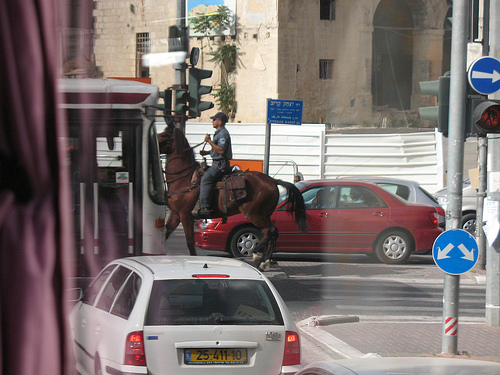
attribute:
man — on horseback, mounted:
[200, 104, 236, 181]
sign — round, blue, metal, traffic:
[434, 228, 480, 271]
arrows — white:
[440, 242, 476, 262]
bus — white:
[21, 85, 165, 265]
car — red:
[226, 185, 438, 268]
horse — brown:
[167, 155, 268, 239]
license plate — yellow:
[176, 349, 256, 367]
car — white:
[106, 269, 285, 373]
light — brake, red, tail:
[277, 331, 310, 372]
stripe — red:
[33, 87, 161, 110]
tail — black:
[271, 172, 316, 242]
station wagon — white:
[94, 251, 286, 374]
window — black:
[154, 287, 262, 315]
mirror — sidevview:
[65, 284, 85, 301]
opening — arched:
[365, 0, 413, 101]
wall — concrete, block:
[89, 7, 134, 74]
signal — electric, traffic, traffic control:
[181, 56, 213, 118]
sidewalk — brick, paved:
[339, 317, 471, 371]